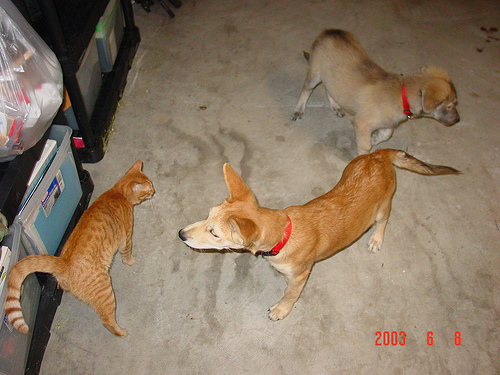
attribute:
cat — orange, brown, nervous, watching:
[4, 161, 156, 338]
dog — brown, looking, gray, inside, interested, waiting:
[179, 146, 463, 322]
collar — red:
[398, 74, 413, 116]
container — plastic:
[76, 34, 102, 117]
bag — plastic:
[2, 1, 64, 163]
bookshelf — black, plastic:
[14, 3, 140, 164]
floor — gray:
[39, 2, 499, 373]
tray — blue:
[23, 149, 79, 258]